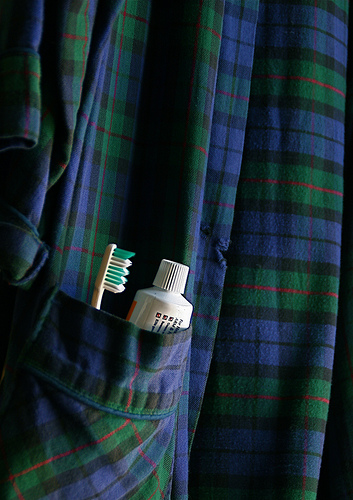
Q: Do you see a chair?
A: No, there are no chairs.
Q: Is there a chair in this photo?
A: No, there are no chairs.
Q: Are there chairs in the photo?
A: No, there are no chairs.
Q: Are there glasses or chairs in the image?
A: No, there are no chairs or glasses.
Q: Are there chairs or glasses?
A: No, there are no chairs or glasses.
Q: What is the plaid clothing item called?
A: The clothing item is a robe.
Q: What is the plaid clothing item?
A: The clothing item is a robe.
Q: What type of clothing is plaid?
A: The clothing is a robe.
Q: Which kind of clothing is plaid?
A: The clothing is a robe.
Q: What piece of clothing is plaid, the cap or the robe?
A: The robe is plaid.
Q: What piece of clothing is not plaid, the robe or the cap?
A: The cap is not plaid.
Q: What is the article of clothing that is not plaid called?
A: The clothing item is a cap.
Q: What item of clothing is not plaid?
A: The clothing item is a cap.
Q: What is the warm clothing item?
A: The clothing item is a robe.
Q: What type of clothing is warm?
A: The clothing is a robe.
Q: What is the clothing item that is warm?
A: The clothing item is a robe.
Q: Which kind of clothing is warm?
A: The clothing is a robe.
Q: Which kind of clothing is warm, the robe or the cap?
A: The robe is warm.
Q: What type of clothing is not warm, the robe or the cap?
A: The cap is not warm.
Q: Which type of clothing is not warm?
A: The clothing is a cap.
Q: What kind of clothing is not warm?
A: The clothing is a cap.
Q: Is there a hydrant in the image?
A: No, there are no fire hydrants.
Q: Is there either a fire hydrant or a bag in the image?
A: No, there are no fire hydrants or bags.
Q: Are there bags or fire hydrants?
A: No, there are no fire hydrants or bags.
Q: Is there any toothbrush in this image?
A: Yes, there is a toothbrush.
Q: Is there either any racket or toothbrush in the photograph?
A: Yes, there is a toothbrush.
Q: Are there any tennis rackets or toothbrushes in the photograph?
A: Yes, there is a toothbrush.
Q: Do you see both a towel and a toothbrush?
A: No, there is a toothbrush but no towels.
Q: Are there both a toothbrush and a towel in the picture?
A: No, there is a toothbrush but no towels.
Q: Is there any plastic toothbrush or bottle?
A: Yes, there is a plastic toothbrush.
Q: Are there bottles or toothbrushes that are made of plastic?
A: Yes, the toothbrush is made of plastic.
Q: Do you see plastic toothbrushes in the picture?
A: Yes, there is a toothbrush that is made of plastic.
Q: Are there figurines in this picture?
A: No, there are no figurines.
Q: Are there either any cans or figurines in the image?
A: No, there are no figurines or cans.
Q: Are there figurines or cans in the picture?
A: No, there are no figurines or cans.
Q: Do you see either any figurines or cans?
A: No, there are no figurines or cans.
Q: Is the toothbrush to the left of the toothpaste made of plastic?
A: Yes, the toothbrush is made of plastic.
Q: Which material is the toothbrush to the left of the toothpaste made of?
A: The toothbrush is made of plastic.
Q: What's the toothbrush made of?
A: The toothbrush is made of plastic.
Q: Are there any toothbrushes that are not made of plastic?
A: No, there is a toothbrush but it is made of plastic.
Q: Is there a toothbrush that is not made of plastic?
A: No, there is a toothbrush but it is made of plastic.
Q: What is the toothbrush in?
A: The toothbrush is in the pocket.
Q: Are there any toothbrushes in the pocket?
A: Yes, there is a toothbrush in the pocket.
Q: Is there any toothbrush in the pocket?
A: Yes, there is a toothbrush in the pocket.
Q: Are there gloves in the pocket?
A: No, there is a toothbrush in the pocket.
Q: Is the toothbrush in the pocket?
A: Yes, the toothbrush is in the pocket.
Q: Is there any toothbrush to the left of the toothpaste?
A: Yes, there is a toothbrush to the left of the toothpaste.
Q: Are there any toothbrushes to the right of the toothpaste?
A: No, the toothbrush is to the left of the toothpaste.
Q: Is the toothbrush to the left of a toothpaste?
A: Yes, the toothbrush is to the left of a toothpaste.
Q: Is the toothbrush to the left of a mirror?
A: No, the toothbrush is to the left of a toothpaste.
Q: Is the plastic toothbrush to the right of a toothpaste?
A: No, the toothbrush is to the left of a toothpaste.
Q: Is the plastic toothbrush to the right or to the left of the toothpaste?
A: The toothbrush is to the left of the toothpaste.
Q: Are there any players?
A: No, there are no players.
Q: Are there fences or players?
A: No, there are no players or fences.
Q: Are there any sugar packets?
A: No, there are no sugar packets.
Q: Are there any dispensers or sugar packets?
A: No, there are no sugar packets or dispensers.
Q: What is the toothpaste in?
A: The toothpaste is in the pocket.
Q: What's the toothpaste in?
A: The toothpaste is in the pocket.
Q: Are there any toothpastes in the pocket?
A: Yes, there is a toothpaste in the pocket.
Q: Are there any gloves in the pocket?
A: No, there is a toothpaste in the pocket.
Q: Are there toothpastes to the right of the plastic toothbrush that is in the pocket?
A: Yes, there is a toothpaste to the right of the toothbrush.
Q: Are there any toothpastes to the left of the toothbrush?
A: No, the toothpaste is to the right of the toothbrush.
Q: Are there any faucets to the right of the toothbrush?
A: No, there is a toothpaste to the right of the toothbrush.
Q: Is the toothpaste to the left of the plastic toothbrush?
A: No, the toothpaste is to the right of the toothbrush.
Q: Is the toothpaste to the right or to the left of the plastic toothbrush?
A: The toothpaste is to the right of the toothbrush.